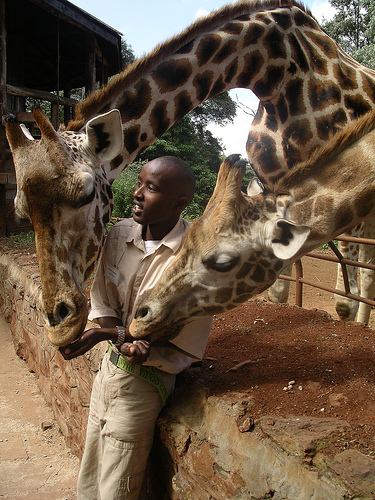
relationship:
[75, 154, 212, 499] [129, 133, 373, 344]
guy sitting between giraffe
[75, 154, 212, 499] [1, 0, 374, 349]
guy sitting between giraffe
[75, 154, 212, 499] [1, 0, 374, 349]
guy between giraffe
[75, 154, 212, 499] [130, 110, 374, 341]
guy between giraffe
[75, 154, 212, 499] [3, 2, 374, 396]
guy sitting between giraffe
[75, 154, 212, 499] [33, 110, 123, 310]
guy sitting between giraffe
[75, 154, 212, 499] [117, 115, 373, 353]
guy sitting between giraffe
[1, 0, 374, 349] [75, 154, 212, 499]
giraffe to left of guy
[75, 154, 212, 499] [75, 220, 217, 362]
guy wearing shirt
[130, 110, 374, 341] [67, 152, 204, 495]
giraffe to right of man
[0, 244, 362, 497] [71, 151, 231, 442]
brick wall in back of of man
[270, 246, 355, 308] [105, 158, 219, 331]
fence between man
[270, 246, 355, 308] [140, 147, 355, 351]
fence between giraffe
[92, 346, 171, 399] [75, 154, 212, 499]
belt on guy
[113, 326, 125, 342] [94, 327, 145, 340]
watch on man's arm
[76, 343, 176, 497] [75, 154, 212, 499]
pants on guy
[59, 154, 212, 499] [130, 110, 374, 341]
guy feeding giraffe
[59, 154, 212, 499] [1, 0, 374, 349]
guy feeding giraffe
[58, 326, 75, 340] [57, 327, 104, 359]
snack from hand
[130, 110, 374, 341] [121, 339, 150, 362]
giraffe from hand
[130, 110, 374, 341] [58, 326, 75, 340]
giraffe getting snack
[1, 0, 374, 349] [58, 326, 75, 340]
giraffe getting snack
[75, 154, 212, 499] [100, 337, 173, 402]
guy wearing a belt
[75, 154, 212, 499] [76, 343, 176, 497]
guy wearing pants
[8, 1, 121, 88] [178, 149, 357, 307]
building next to pen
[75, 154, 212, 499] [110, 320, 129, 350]
guy wearing a watch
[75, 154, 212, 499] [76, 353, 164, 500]
guy wearing pants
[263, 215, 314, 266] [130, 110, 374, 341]
ear on giraffe